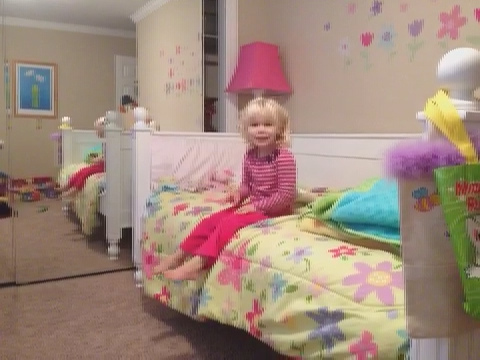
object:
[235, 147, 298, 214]
shirt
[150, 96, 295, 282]
child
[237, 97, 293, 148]
hair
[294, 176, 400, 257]
blanket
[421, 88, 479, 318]
bag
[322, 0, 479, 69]
flowers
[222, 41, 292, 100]
lamp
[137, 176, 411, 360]
comforter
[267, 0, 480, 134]
wall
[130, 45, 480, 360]
bed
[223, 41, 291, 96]
lampshade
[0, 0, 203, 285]
mirror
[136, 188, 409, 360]
bedspread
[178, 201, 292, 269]
pants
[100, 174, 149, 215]
bad sentence